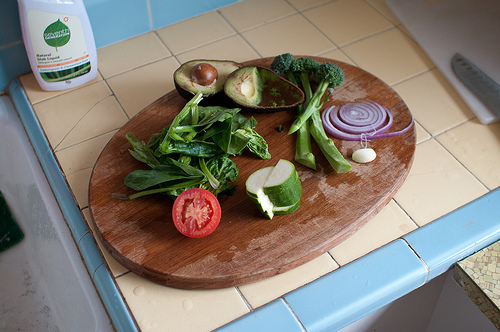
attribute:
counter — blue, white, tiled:
[15, 2, 498, 327]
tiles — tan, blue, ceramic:
[30, 84, 138, 143]